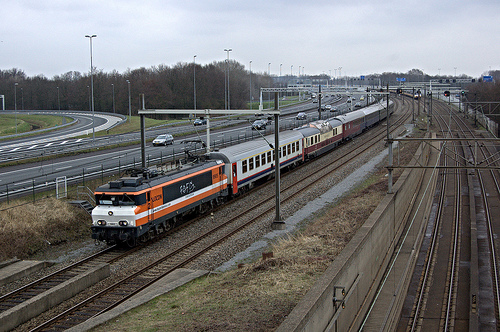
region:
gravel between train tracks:
[66, 249, 183, 281]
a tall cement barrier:
[294, 187, 406, 328]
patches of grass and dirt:
[186, 267, 302, 330]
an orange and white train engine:
[88, 146, 238, 231]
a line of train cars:
[207, 97, 418, 194]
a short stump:
[256, 243, 277, 267]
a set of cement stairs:
[66, 190, 98, 230]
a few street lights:
[211, 30, 323, 122]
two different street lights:
[438, 85, 470, 102]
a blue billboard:
[393, 70, 410, 84]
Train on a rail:
[82, 78, 412, 248]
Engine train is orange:
[87, 149, 238, 244]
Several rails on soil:
[9, 94, 497, 330]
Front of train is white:
[86, 196, 139, 236]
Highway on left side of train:
[1, 121, 301, 183]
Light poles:
[15, 25, 235, 115]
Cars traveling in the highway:
[147, 105, 307, 146]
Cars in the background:
[326, 92, 363, 107]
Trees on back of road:
[6, 57, 241, 107]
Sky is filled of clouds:
[1, 5, 494, 72]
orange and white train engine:
[82, 155, 243, 242]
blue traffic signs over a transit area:
[386, 70, 498, 95]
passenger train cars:
[219, 130, 340, 187]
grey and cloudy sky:
[306, 1, 477, 53]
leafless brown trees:
[135, 68, 243, 99]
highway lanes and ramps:
[17, 122, 116, 165]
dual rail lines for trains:
[41, 261, 164, 294]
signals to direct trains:
[327, 285, 355, 314]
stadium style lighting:
[78, 23, 108, 115]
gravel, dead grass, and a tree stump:
[223, 238, 304, 295]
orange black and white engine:
[84, 153, 232, 248]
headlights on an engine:
[94, 215, 129, 228]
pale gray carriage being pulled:
[206, 126, 305, 203]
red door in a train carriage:
[229, 160, 239, 194]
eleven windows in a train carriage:
[237, 139, 303, 174]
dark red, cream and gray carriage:
[296, 113, 344, 162]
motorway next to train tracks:
[0, 86, 377, 197]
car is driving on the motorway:
[151, 130, 176, 147]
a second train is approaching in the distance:
[380, 84, 422, 101]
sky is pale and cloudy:
[0, 2, 498, 80]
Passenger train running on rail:
[78, 78, 414, 255]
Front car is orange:
[87, 146, 239, 246]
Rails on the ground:
[0, 236, 216, 321]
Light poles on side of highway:
[76, 25, 366, 90]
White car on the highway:
[146, 126, 176, 146]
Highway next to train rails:
[12, 125, 292, 195]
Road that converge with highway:
[0, 96, 125, 141]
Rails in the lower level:
[388, 110, 495, 328]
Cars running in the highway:
[302, 82, 372, 114]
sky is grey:
[0, 0, 495, 73]